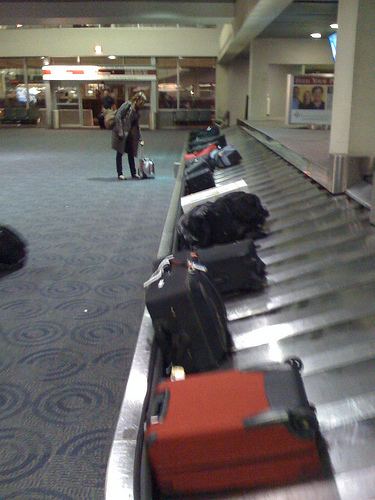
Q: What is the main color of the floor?
A: Gray.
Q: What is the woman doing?
A: Waiting for luggage.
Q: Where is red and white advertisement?
A: On the left of conveyor.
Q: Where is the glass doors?
A: To the left of the woman.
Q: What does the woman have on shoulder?
A: Pocketbook.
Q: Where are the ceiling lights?
A: Above the advertisement.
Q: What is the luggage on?
A: Conveyor belt.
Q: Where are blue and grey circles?
A: On floor.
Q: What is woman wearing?
A: Coat.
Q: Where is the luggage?
A: On the conveyor belt.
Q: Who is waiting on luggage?
A: A blonde woman.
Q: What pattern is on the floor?
A: Circles.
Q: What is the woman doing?
A: Waiting for her bags.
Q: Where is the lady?
A: The airport.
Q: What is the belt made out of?
A: Metal.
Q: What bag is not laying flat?
A: Black suitcase.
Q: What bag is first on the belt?
A: Orange suitcase.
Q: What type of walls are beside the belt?
A: Solid white.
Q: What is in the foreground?
A: Red suitcase with wheels.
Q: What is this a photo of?
A: The baggage claim area.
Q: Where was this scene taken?
A: Airport.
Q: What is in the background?
A: Shop at an airport.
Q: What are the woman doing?
A: Picking up luggage.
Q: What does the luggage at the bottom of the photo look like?
A: A red luggage with a black handle.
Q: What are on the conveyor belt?
A: A bunch of luggage waiting to be claimed.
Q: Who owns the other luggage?
A: No indication.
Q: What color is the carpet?
A: Blue.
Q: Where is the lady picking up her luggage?
A: Baggage claim.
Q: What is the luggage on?
A: Conveyor belt.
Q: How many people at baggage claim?
A: One.